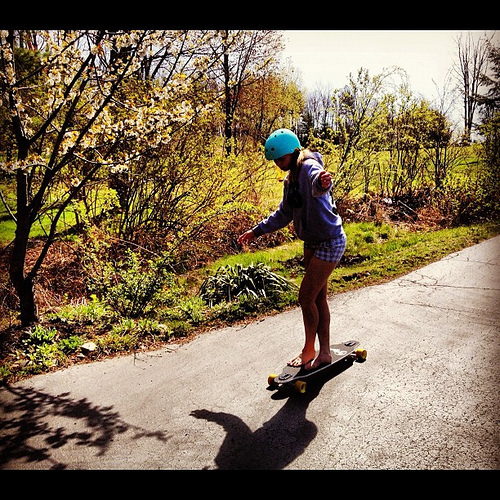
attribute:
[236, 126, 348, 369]
girl — skateboarding, skateboarding outsid, barefoot, young, without shoes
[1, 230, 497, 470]
sidewalk — dark gray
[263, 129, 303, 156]
helmet — blue, light blue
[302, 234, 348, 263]
shorts — checkered, plaid, checked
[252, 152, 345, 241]
hoodie — blue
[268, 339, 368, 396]
skateboard — black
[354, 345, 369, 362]
wheel — yellow, round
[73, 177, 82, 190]
blossom — white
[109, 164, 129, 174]
blossom — white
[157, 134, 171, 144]
blossom — white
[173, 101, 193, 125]
blossom — white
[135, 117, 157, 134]
blossom — white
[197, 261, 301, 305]
plant — green, large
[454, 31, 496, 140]
tree — tall, dead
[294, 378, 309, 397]
wheel — yellow, round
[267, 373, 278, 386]
wheel — yellow, round